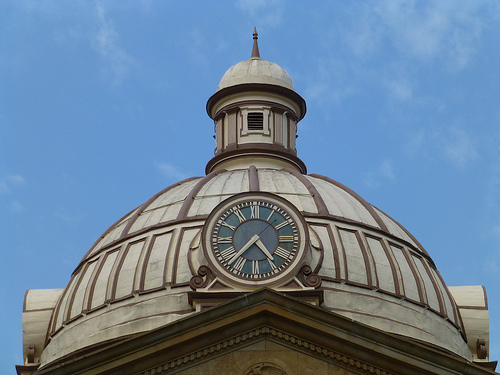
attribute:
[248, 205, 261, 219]
numeral 12 — roman